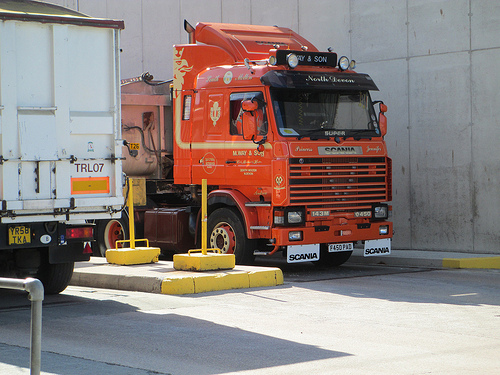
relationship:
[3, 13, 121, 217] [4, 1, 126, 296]
rear of truck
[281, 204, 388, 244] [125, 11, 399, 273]
headlights on truck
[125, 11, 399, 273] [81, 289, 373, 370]
truck has a shadow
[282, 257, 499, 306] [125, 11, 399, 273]
shadow of a truck